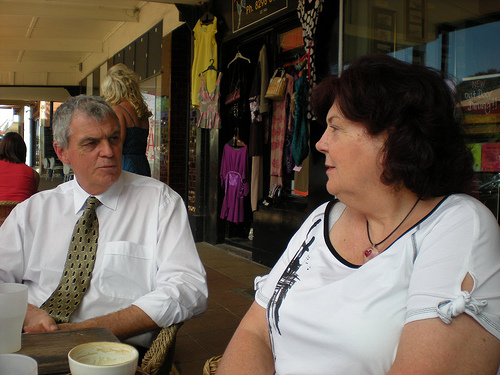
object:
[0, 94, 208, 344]
man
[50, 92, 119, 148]
hair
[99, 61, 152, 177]
woman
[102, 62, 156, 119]
hair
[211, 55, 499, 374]
woman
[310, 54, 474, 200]
hair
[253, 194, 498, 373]
shirt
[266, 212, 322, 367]
design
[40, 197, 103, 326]
tie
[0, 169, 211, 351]
shirt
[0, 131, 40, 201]
woman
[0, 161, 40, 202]
shirt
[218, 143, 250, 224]
shirt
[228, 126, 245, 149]
hanger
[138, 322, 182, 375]
chair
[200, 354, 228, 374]
chair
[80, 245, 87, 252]
spots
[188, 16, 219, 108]
dress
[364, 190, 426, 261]
necklace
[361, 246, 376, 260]
pendant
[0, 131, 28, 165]
hair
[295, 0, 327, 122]
dress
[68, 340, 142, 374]
cup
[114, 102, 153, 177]
dress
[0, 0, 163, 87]
roof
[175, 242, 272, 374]
sidewalk